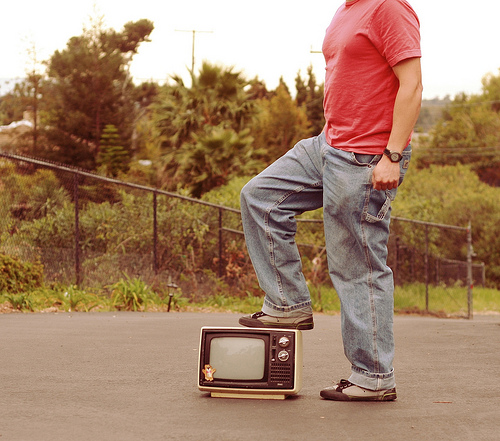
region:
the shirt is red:
[311, 9, 411, 160]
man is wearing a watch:
[361, 114, 444, 199]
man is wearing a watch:
[358, 139, 426, 181]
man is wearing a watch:
[370, 118, 432, 168]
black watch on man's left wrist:
[381, 150, 406, 163]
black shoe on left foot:
[317, 374, 401, 401]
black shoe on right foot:
[240, 312, 316, 326]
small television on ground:
[202, 328, 304, 401]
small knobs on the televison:
[277, 330, 290, 363]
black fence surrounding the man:
[0, 156, 80, 303]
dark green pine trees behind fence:
[42, 33, 138, 146]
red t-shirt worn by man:
[320, 2, 415, 147]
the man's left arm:
[372, 4, 416, 199]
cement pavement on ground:
[442, 332, 497, 418]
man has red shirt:
[291, 11, 425, 148]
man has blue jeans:
[232, 133, 437, 403]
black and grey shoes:
[251, 303, 401, 427]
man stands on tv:
[195, 318, 347, 412]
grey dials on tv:
[247, 331, 311, 379]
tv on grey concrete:
[165, 321, 307, 399]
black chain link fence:
[4, 187, 436, 309]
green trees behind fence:
[4, 50, 291, 251]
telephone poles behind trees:
[161, 4, 251, 102]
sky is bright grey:
[165, 10, 356, 45]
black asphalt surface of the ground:
[426, 330, 477, 407]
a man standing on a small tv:
[193, 135, 400, 403]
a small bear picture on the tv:
[200, 363, 217, 385]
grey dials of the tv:
[277, 335, 292, 360]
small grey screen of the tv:
[203, 333, 270, 386]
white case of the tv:
[291, 333, 304, 393]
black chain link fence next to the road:
[44, 166, 181, 281]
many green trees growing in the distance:
[26, 61, 269, 208]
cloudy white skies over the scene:
[219, 8, 283, 62]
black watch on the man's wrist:
[380, 143, 402, 165]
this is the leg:
[228, 155, 294, 295]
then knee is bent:
[240, 173, 295, 218]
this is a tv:
[188, 323, 305, 393]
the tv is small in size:
[196, 321, 295, 398]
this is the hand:
[374, 67, 426, 152]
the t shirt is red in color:
[312, 17, 375, 127]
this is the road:
[45, 325, 175, 433]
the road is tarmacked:
[48, 320, 169, 435]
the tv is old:
[200, 328, 302, 389]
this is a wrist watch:
[378, 145, 405, 160]